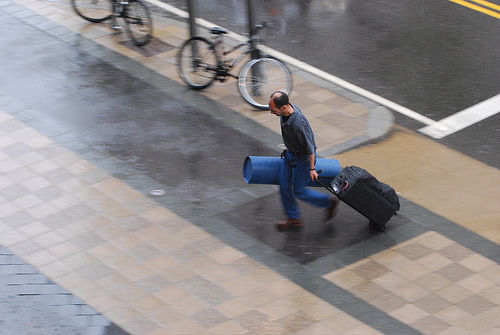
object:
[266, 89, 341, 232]
man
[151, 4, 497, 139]
road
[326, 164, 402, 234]
suitcase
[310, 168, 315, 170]
watch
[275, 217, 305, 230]
shoes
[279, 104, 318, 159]
shirt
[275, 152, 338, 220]
jeans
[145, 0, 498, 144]
lines painted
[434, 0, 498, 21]
lines painted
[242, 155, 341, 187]
container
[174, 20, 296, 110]
bicycle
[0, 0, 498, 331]
sidewalk